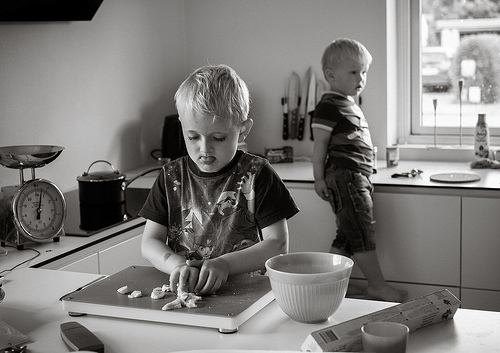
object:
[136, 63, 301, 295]
boy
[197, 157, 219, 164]
tongue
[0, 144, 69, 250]
scale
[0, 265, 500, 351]
counter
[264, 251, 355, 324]
bowl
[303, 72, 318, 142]
knives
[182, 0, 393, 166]
wall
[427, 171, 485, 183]
plate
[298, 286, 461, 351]
box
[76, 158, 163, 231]
pot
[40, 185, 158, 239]
stove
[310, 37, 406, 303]
boy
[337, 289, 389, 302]
stool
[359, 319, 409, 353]
cup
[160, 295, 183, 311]
food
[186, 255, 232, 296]
hands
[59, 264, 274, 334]
chopping board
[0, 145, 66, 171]
bowl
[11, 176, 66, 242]
dial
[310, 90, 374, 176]
clothes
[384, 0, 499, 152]
window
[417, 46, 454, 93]
car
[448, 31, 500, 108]
hedges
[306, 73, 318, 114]
blades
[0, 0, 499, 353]
kitchen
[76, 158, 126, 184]
lid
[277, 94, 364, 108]
rack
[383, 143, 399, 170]
jar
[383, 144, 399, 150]
lid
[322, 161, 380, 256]
shorts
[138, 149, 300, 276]
t-shirt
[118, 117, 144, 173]
shadow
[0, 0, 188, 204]
wall